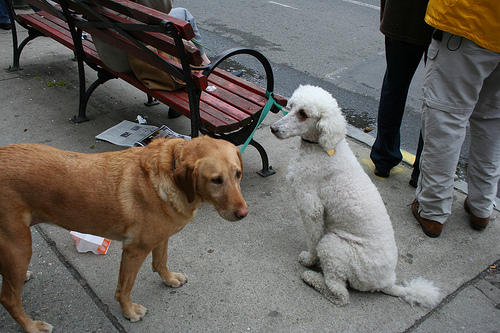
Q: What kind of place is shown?
A: It is a sidewalk.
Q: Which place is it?
A: It is a sidewalk.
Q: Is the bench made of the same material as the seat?
A: Yes, both the bench and the seat are made of wood.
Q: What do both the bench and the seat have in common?
A: The material, both the bench and the seat are wooden.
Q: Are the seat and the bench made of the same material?
A: Yes, both the seat and the bench are made of wood.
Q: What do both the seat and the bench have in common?
A: The material, both the seat and the bench are wooden.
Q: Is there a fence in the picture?
A: No, there are no fences.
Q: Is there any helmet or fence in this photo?
A: No, there are no fences or helmets.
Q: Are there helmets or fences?
A: No, there are no fences or helmets.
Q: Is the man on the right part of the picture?
A: Yes, the man is on the right of the image.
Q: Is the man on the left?
A: No, the man is on the right of the image.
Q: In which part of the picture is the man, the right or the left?
A: The man is on the right of the image.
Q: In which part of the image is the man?
A: The man is on the right of the image.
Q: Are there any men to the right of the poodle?
A: Yes, there is a man to the right of the poodle.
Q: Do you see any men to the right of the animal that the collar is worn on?
A: Yes, there is a man to the right of the poodle.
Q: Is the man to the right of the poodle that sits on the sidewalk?
A: Yes, the man is to the right of the poodle.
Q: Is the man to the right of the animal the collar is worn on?
A: Yes, the man is to the right of the poodle.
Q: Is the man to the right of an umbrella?
A: No, the man is to the right of the poodle.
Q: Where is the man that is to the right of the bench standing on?
A: The man is standing on the sidewalk.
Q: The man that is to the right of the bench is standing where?
A: The man is standing on the sidewalk.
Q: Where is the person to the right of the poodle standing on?
A: The man is standing on the sidewalk.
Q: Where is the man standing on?
A: The man is standing on the sidewalk.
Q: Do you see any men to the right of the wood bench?
A: Yes, there is a man to the right of the bench.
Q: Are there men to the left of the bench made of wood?
A: No, the man is to the right of the bench.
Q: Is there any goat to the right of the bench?
A: No, there is a man to the right of the bench.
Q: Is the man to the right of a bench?
A: Yes, the man is to the right of a bench.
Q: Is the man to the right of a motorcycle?
A: No, the man is to the right of a bench.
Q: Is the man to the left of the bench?
A: No, the man is to the right of the bench.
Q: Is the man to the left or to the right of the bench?
A: The man is to the right of the bench.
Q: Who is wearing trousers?
A: The man is wearing trousers.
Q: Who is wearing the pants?
A: The man is wearing trousers.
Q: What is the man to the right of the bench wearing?
A: The man is wearing trousers.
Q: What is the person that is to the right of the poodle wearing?
A: The man is wearing trousers.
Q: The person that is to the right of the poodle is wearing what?
A: The man is wearing trousers.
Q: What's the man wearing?
A: The man is wearing trousers.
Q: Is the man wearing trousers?
A: Yes, the man is wearing trousers.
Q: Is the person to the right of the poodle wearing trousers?
A: Yes, the man is wearing trousers.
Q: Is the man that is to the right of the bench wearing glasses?
A: No, the man is wearing trousers.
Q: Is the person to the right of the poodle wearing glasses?
A: No, the man is wearing trousers.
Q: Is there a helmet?
A: No, there are no helmets.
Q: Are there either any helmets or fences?
A: No, there are no helmets or fences.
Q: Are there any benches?
A: Yes, there is a bench.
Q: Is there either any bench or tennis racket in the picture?
A: Yes, there is a bench.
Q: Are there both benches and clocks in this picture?
A: No, there is a bench but no clocks.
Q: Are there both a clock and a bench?
A: No, there is a bench but no clocks.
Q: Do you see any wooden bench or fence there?
A: Yes, there is a wood bench.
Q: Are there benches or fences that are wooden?
A: Yes, the bench is wooden.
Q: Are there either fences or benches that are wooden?
A: Yes, the bench is wooden.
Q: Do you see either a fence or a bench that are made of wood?
A: Yes, the bench is made of wood.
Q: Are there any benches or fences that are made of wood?
A: Yes, the bench is made of wood.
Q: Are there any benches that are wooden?
A: Yes, there is a wood bench.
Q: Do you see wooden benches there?
A: Yes, there is a wood bench.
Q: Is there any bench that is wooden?
A: Yes, there is a bench that is wooden.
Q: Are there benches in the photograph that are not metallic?
A: Yes, there is a wooden bench.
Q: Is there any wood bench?
A: Yes, there is a bench that is made of wood.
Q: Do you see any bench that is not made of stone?
A: Yes, there is a bench that is made of wood.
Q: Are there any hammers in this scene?
A: No, there are no hammers.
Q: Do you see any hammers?
A: No, there are no hammers.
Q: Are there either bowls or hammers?
A: No, there are no hammers or bowls.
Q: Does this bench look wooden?
A: Yes, the bench is wooden.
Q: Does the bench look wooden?
A: Yes, the bench is wooden.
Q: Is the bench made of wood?
A: Yes, the bench is made of wood.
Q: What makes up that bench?
A: The bench is made of wood.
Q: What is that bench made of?
A: The bench is made of wood.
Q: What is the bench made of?
A: The bench is made of wood.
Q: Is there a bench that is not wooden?
A: No, there is a bench but it is wooden.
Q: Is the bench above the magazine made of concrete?
A: No, the bench is made of wood.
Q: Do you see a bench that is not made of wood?
A: No, there is a bench but it is made of wood.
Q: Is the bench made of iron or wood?
A: The bench is made of wood.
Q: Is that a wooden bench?
A: Yes, that is a wooden bench.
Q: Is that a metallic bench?
A: No, that is a wooden bench.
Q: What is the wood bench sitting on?
A: The bench is sitting on the sidewalk.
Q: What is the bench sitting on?
A: The bench is sitting on the sidewalk.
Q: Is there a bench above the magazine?
A: Yes, there is a bench above the magazine.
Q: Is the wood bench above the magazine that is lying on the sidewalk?
A: Yes, the bench is above the magazine.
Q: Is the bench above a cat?
A: No, the bench is above the magazine.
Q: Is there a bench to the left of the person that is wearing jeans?
A: Yes, there is a bench to the left of the person.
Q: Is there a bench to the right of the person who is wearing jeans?
A: No, the bench is to the left of the person.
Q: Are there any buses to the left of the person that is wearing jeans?
A: No, there is a bench to the left of the person.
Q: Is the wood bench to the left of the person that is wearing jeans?
A: Yes, the bench is to the left of the person.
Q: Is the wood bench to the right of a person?
A: No, the bench is to the left of a person.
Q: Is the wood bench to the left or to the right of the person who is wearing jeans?
A: The bench is to the left of the person.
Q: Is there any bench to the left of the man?
A: Yes, there is a bench to the left of the man.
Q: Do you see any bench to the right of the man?
A: No, the bench is to the left of the man.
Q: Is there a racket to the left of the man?
A: No, there is a bench to the left of the man.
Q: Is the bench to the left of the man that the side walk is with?
A: Yes, the bench is to the left of the man.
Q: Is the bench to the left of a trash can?
A: No, the bench is to the left of the man.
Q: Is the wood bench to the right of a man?
A: No, the bench is to the left of a man.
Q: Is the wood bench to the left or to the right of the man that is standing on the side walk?
A: The bench is to the left of the man.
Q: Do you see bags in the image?
A: Yes, there is a bag.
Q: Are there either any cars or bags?
A: Yes, there is a bag.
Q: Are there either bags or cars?
A: Yes, there is a bag.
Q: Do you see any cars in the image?
A: No, there are no cars.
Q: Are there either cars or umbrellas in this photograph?
A: No, there are no cars or umbrellas.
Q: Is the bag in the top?
A: Yes, the bag is in the top of the image.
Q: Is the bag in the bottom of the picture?
A: No, the bag is in the top of the image.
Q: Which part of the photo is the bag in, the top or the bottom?
A: The bag is in the top of the image.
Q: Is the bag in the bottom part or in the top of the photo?
A: The bag is in the top of the image.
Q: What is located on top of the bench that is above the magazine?
A: The bag is on top of the bench.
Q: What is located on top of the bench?
A: The bag is on top of the bench.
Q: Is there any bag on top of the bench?
A: Yes, there is a bag on top of the bench.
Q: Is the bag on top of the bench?
A: Yes, the bag is on top of the bench.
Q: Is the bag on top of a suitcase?
A: No, the bag is on top of the bench.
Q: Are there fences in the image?
A: No, there are no fences.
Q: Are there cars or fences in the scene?
A: No, there are no fences or cars.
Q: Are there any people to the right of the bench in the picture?
A: Yes, there is a person to the right of the bench.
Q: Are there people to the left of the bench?
A: No, the person is to the right of the bench.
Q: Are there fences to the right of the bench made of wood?
A: No, there is a person to the right of the bench.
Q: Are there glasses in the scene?
A: No, there are no glasses.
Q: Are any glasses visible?
A: No, there are no glasses.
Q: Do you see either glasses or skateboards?
A: No, there are no glasses or skateboards.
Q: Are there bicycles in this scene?
A: No, there are no bicycles.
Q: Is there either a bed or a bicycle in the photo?
A: No, there are no bicycles or beds.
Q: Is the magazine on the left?
A: Yes, the magazine is on the left of the image.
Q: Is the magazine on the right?
A: No, the magazine is on the left of the image.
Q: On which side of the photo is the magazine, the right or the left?
A: The magazine is on the left of the image.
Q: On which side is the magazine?
A: The magazine is on the left of the image.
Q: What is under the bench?
A: The magazine is under the bench.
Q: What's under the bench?
A: The magazine is under the bench.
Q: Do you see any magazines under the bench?
A: Yes, there is a magazine under the bench.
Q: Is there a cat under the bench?
A: No, there is a magazine under the bench.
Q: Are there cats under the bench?
A: No, there is a magazine under the bench.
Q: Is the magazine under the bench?
A: Yes, the magazine is under the bench.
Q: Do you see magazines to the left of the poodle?
A: Yes, there is a magazine to the left of the poodle.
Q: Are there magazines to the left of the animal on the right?
A: Yes, there is a magazine to the left of the poodle.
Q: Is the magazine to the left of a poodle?
A: Yes, the magazine is to the left of a poodle.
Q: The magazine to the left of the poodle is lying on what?
A: The magazine is lying on the sidewalk.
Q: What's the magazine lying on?
A: The magazine is lying on the sidewalk.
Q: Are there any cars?
A: No, there are no cars.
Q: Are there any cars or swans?
A: No, there are no cars or swans.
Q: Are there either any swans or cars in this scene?
A: No, there are no cars or swans.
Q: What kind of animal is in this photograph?
A: The animal is a poodle.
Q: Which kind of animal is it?
A: The animal is a poodle.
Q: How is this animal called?
A: This is a poodle.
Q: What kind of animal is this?
A: This is a poodle.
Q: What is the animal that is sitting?
A: The animal is a poodle.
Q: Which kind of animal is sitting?
A: The animal is a poodle.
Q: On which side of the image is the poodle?
A: The poodle is on the right of the image.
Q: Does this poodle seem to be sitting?
A: Yes, the poodle is sitting.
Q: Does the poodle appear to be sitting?
A: Yes, the poodle is sitting.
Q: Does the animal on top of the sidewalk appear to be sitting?
A: Yes, the poodle is sitting.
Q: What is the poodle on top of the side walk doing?
A: The poodle is sitting.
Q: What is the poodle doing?
A: The poodle is sitting.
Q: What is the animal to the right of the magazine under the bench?
A: The animal is a poodle.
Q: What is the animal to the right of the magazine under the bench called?
A: The animal is a poodle.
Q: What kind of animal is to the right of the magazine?
A: The animal is a poodle.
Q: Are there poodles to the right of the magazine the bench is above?
A: Yes, there is a poodle to the right of the magazine.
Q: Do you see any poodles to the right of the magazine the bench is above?
A: Yes, there is a poodle to the right of the magazine.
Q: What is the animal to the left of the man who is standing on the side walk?
A: The animal is a poodle.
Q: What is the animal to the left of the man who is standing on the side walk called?
A: The animal is a poodle.